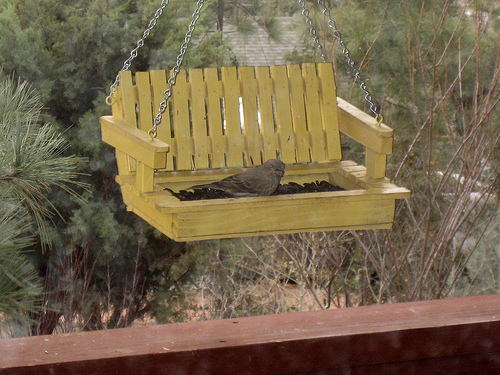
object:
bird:
[184, 159, 286, 197]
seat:
[134, 157, 413, 213]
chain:
[296, 0, 328, 64]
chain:
[110, 0, 173, 90]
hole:
[216, 335, 228, 345]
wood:
[1, 292, 500, 375]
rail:
[0, 294, 499, 374]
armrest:
[334, 96, 393, 180]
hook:
[145, 130, 159, 139]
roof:
[190, 0, 318, 67]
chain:
[318, 0, 378, 116]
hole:
[231, 318, 240, 324]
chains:
[148, 0, 211, 136]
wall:
[1, 290, 500, 374]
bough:
[2, 67, 94, 340]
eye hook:
[373, 115, 385, 126]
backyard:
[0, 0, 499, 340]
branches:
[215, 0, 498, 321]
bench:
[98, 62, 411, 242]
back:
[120, 62, 343, 172]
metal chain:
[108, 0, 171, 96]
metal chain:
[314, 0, 388, 127]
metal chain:
[295, 0, 327, 66]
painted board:
[0, 292, 499, 374]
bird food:
[177, 171, 343, 196]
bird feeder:
[99, 62, 412, 243]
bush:
[268, 0, 499, 313]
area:
[0, 0, 499, 375]